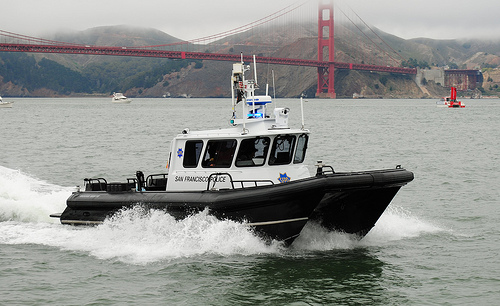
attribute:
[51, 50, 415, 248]
boat — black, white, a police boat, police boat, moving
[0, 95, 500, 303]
water — dark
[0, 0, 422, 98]
bridge — golden gate bridge, red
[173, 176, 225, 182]
letters — black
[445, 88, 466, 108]
boat — red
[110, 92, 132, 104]
boat — white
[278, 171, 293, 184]
star — blue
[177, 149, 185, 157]
star — blue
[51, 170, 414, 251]
bottom — black